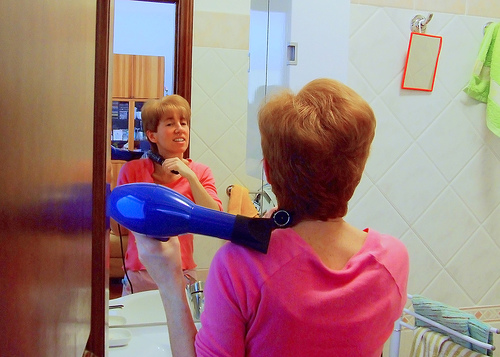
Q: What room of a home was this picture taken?
A: Bathroom.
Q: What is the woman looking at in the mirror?
A: Herself.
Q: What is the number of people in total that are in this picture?
A: 1.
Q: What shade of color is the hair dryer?
A: Blue.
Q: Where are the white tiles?
A: On the wall of the shower.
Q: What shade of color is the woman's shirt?
A: Pink.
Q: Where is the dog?
A: There is no dog.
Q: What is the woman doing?
A: Styling her hair.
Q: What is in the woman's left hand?
A: Blow dryer.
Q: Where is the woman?
A: In front of a mirror.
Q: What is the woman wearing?
A: A pink top.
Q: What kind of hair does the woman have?
A: Short, light brown.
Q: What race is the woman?
A: White.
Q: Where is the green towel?
A: On the tiled wall.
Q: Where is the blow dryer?
A: In the woman's hand.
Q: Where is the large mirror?
A: In front of the woman.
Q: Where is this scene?
A: In a house.